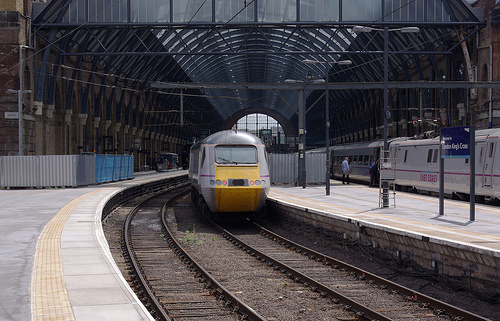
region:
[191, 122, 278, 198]
this is a train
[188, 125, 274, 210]
the train is moving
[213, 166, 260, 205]
the front is yellow in color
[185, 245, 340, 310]
these are the rails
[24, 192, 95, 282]
this is the pavement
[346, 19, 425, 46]
these are street lights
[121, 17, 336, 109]
this is a tunnel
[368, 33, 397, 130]
the pole is straight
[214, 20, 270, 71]
the top is metallic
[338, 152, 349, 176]
the man is standing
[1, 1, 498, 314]
the scene is at a subway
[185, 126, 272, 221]
a train is approaching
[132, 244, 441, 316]
there are two railwaylines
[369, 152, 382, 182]
some people are boarding the train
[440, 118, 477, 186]
the sign is blue in colour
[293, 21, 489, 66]
the lampstands are off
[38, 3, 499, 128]
the roof is dome shaped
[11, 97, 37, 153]
the wall is made of bricks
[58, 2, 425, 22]
the roof has some winndowpanes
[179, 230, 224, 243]
some grass are growing on the railway track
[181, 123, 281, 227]
gray and yellow train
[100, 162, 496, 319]
brown train tracks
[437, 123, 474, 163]
blue sign with white lettering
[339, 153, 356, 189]
man in blue shirt and dark pants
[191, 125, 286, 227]
train with two red lights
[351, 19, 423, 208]
gray street lamp with two lights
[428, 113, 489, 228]
blue sign with dark posts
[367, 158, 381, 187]
man part of the way inside a train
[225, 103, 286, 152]
window showing city outside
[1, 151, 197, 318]
concrete waiting area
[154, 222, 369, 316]
railway track at the railway station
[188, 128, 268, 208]
train on the railway station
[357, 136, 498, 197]
white colour train in the railway station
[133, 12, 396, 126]
a shed of railway station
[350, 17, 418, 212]
electric post with lamp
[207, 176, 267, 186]
head light with indicator infront of the train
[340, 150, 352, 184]
a person is standing in the platform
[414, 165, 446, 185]
numbers and letter written in the train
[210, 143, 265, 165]
front glass with wiper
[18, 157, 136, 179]
white colour and blue colour sheet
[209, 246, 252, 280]
gravel on the train track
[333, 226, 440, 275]
cables at side of platform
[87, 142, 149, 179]
large blue container bins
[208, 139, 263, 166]
large silver mirror in front of train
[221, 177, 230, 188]
tiny red light on train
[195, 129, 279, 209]
silver train on the track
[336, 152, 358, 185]
man standing on platform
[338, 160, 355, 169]
man wearing blue shirt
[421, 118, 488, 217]
blue metal sign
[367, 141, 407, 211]
silver ladder leaning against post